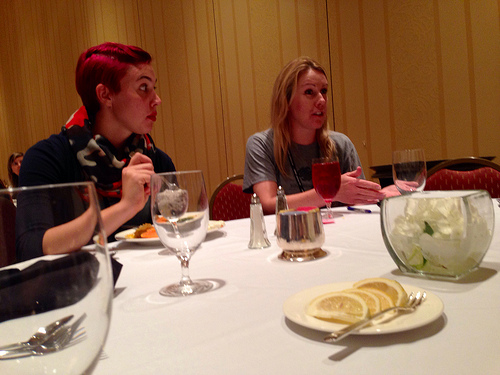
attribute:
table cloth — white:
[1, 192, 499, 373]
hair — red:
[74, 44, 153, 121]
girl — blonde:
[269, 56, 340, 174]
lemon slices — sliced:
[312, 282, 405, 326]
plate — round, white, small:
[285, 278, 445, 339]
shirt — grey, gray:
[244, 126, 360, 210]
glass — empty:
[389, 151, 430, 199]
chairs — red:
[207, 159, 499, 222]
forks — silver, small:
[326, 293, 429, 349]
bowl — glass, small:
[380, 187, 496, 281]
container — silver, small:
[278, 211, 323, 257]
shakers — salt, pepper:
[246, 189, 291, 249]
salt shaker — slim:
[247, 192, 270, 250]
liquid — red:
[313, 164, 342, 197]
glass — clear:
[150, 174, 206, 248]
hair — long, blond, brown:
[271, 56, 338, 171]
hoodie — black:
[16, 131, 172, 262]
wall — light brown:
[2, 0, 499, 196]